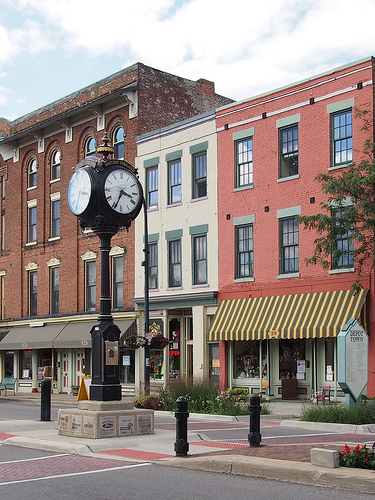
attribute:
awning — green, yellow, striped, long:
[207, 287, 370, 343]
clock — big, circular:
[66, 130, 143, 403]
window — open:
[276, 114, 303, 184]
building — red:
[215, 55, 374, 399]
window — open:
[189, 139, 210, 204]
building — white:
[134, 108, 218, 398]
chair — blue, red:
[314, 384, 331, 405]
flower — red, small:
[343, 443, 351, 454]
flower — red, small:
[354, 444, 359, 453]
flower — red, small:
[340, 450, 345, 457]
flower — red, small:
[362, 456, 368, 460]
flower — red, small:
[360, 444, 365, 451]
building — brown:
[0, 60, 236, 397]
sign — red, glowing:
[167, 349, 180, 357]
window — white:
[48, 190, 62, 243]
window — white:
[25, 197, 39, 250]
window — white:
[24, 263, 40, 318]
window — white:
[25, 155, 39, 193]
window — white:
[48, 148, 62, 186]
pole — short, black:
[174, 396, 189, 457]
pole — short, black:
[249, 393, 261, 447]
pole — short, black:
[40, 380, 52, 424]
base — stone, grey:
[55, 399, 156, 437]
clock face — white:
[103, 168, 140, 215]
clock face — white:
[68, 169, 92, 216]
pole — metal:
[90, 225, 121, 400]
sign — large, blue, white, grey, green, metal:
[336, 317, 369, 407]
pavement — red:
[1, 419, 374, 492]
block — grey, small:
[310, 447, 338, 468]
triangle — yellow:
[75, 377, 90, 402]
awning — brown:
[1, 318, 137, 351]